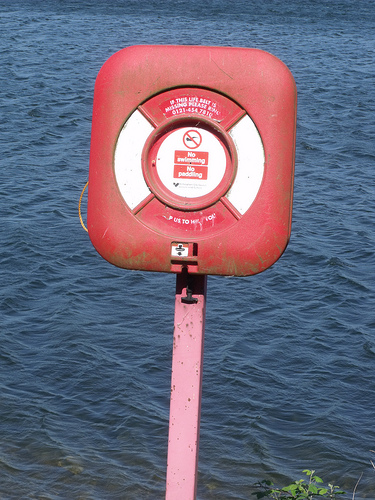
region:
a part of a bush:
[257, 459, 355, 499]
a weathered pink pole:
[147, 276, 215, 499]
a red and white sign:
[73, 33, 313, 286]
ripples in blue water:
[213, 279, 366, 455]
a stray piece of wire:
[70, 178, 98, 244]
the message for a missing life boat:
[153, 87, 228, 128]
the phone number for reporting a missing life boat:
[160, 88, 221, 125]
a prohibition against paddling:
[174, 163, 214, 179]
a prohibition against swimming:
[171, 149, 210, 166]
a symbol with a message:
[179, 127, 203, 154]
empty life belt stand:
[83, 44, 295, 498]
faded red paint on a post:
[154, 270, 208, 497]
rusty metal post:
[160, 278, 203, 493]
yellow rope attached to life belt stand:
[73, 173, 90, 235]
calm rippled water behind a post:
[2, 2, 373, 497]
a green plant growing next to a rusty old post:
[267, 459, 340, 499]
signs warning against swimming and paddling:
[164, 125, 211, 180]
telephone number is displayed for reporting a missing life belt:
[160, 91, 220, 121]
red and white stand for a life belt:
[85, 41, 300, 277]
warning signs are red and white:
[170, 147, 211, 179]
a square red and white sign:
[83, 41, 299, 274]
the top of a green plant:
[248, 466, 340, 498]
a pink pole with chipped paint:
[157, 275, 207, 498]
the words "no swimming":
[173, 149, 209, 165]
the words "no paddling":
[172, 165, 206, 180]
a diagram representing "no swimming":
[181, 127, 204, 149]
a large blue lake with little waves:
[2, 6, 371, 476]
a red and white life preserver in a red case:
[82, 38, 298, 277]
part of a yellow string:
[71, 177, 92, 240]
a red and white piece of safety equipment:
[82, 42, 295, 282]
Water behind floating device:
[17, 82, 187, 263]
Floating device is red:
[87, 45, 295, 279]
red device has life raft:
[89, 42, 296, 278]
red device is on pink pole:
[83, 39, 288, 395]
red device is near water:
[71, 43, 301, 283]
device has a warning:
[180, 128, 202, 153]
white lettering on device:
[161, 94, 223, 122]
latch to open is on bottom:
[162, 237, 205, 309]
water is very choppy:
[230, 313, 344, 465]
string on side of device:
[71, 172, 97, 234]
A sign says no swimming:
[172, 125, 211, 164]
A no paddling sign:
[171, 163, 210, 180]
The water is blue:
[25, 9, 95, 59]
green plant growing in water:
[247, 466, 347, 499]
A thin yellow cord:
[70, 173, 88, 234]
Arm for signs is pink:
[165, 287, 207, 498]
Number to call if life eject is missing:
[159, 96, 221, 117]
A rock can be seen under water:
[46, 452, 94, 479]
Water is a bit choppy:
[298, 14, 370, 100]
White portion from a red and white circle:
[227, 116, 265, 215]